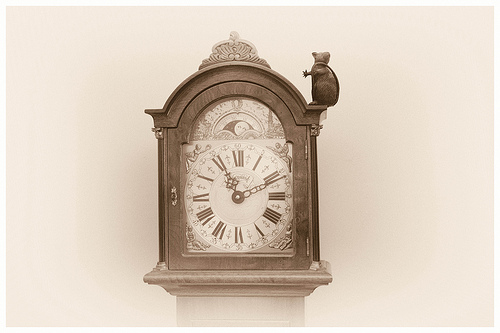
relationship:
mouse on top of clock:
[301, 50, 341, 108] [125, 17, 355, 328]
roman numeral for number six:
[231, 224, 243, 244] [230, 225, 243, 245]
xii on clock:
[229, 147, 246, 169] [142, 15, 347, 325]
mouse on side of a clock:
[301, 50, 341, 108] [176, 142, 295, 250]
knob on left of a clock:
[166, 184, 178, 208] [143, 29, 340, 299]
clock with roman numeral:
[143, 29, 340, 299] [228, 140, 245, 169]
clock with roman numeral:
[143, 29, 340, 299] [250, 147, 266, 173]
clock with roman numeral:
[143, 29, 340, 299] [260, 165, 282, 186]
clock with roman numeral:
[143, 29, 340, 299] [261, 205, 283, 226]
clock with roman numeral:
[143, 29, 340, 299] [208, 217, 230, 242]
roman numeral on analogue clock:
[262, 207, 282, 224] [184, 96, 293, 256]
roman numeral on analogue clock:
[252, 154, 264, 172] [184, 96, 293, 256]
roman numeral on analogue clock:
[264, 170, 279, 182] [184, 96, 293, 256]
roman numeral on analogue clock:
[234, 226, 243, 244] [184, 96, 293, 256]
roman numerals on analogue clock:
[211, 218, 226, 242] [184, 96, 293, 256]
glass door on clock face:
[175, 98, 298, 258] [178, 145, 294, 252]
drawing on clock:
[181, 223, 201, 255] [142, 15, 347, 325]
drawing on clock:
[193, 90, 270, 145] [71, 30, 385, 331]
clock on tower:
[84, 2, 406, 326] [144, 30, 339, 328]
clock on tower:
[143, 29, 340, 299] [144, 30, 339, 328]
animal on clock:
[302, 50, 337, 107] [181, 133, 298, 263]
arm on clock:
[242, 181, 264, 198] [175, 87, 302, 241]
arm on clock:
[220, 170, 241, 194] [175, 87, 302, 241]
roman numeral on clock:
[251, 151, 262, 171] [179, 140, 290, 257]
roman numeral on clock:
[266, 169, 279, 182] [179, 140, 290, 257]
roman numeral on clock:
[268, 190, 286, 200] [179, 140, 290, 257]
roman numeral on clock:
[262, 207, 281, 222] [179, 140, 290, 257]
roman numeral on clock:
[253, 223, 265, 238] [179, 140, 290, 257]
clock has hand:
[143, 29, 340, 299] [235, 163, 287, 202]